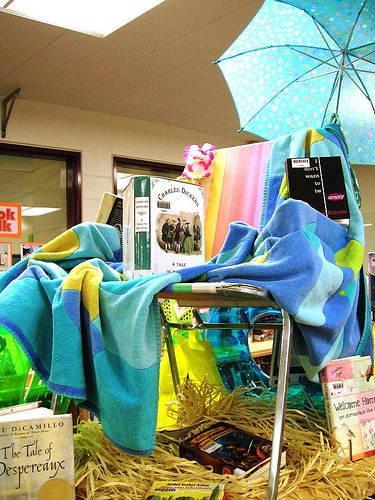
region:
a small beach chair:
[99, 127, 323, 461]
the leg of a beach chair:
[260, 379, 290, 492]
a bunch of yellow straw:
[300, 443, 343, 492]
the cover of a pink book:
[306, 366, 371, 457]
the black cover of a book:
[193, 416, 280, 487]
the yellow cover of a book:
[143, 474, 212, 497]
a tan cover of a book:
[6, 419, 65, 491]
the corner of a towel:
[121, 428, 160, 457]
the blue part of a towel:
[96, 367, 144, 416]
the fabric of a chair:
[176, 272, 211, 296]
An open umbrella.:
[210, 1, 373, 170]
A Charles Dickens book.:
[131, 173, 206, 282]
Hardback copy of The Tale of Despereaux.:
[0, 402, 79, 499]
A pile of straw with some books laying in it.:
[72, 376, 374, 498]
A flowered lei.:
[180, 140, 216, 182]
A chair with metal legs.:
[163, 124, 364, 499]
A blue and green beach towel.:
[0, 122, 374, 457]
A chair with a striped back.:
[147, 125, 367, 498]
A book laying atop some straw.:
[177, 417, 288, 487]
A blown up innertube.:
[204, 309, 326, 414]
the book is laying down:
[178, 421, 286, 479]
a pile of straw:
[68, 380, 373, 497]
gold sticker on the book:
[37, 479, 73, 498]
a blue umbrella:
[212, 0, 371, 166]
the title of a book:
[0, 441, 66, 490]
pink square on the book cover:
[321, 360, 353, 377]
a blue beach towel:
[1, 129, 373, 452]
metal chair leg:
[266, 306, 291, 498]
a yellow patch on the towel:
[62, 263, 103, 321]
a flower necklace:
[183, 142, 214, 183]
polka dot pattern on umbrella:
[226, 68, 309, 115]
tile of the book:
[3, 448, 81, 481]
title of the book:
[322, 398, 373, 415]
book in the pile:
[148, 420, 271, 478]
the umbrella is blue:
[278, 89, 324, 113]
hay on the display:
[308, 470, 346, 487]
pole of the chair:
[275, 316, 280, 496]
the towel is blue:
[250, 262, 323, 297]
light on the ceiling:
[55, 2, 143, 41]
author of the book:
[15, 420, 60, 433]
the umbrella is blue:
[299, 95, 316, 112]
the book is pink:
[363, 401, 371, 413]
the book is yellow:
[185, 488, 198, 496]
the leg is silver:
[276, 340, 292, 375]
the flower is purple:
[185, 142, 210, 157]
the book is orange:
[353, 449, 361, 461]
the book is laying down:
[148, 474, 190, 494]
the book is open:
[27, 399, 74, 429]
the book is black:
[325, 166, 336, 181]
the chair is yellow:
[210, 190, 216, 204]